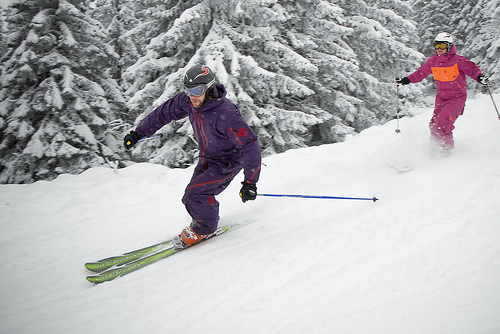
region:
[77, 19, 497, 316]
two people skiing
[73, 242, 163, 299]
yellow and gray skiis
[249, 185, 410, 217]
a long blue ski pole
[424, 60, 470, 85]
an orange square on a snowsuit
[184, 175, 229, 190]
red stripes on snow pants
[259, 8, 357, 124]
pine trees laden with snow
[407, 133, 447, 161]
snow spraying into the air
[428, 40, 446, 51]
orange snowgoogles on a face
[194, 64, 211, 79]
a red squiggle on a helmet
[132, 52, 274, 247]
a man wearing a purple snowsuit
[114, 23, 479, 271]
two skiers on slope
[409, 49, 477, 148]
pink and orange snow suit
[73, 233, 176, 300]
two skis on ground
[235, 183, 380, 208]
pole in black glove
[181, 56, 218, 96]
helmet on skiers head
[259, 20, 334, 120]
snow on tree branches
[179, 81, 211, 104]
goggles on skiers face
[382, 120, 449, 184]
snow spraying in the air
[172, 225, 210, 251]
orange boots on skis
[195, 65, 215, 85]
red design on helmet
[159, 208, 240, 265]
the shoes is red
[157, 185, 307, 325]
the shoes is red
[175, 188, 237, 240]
the shoes is red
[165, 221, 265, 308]
the shoes is red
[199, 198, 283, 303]
the shoes is red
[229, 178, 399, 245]
the stick is blue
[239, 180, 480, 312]
the stick is blue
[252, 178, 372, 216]
the stick is blue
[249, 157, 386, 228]
the stick is blue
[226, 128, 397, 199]
the stick is blue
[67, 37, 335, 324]
man on green and gray skiis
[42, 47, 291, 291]
man wearing purple ski suit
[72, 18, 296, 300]
man wearing orange ski shoes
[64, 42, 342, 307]
man wearing black helmet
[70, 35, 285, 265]
man wearing white goggles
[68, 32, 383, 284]
man holding blue ski poles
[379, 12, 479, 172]
man wearing white helmet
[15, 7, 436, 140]
trees covered in snow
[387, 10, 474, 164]
man wearing pink ski suit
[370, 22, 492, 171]
man holding white ski poles